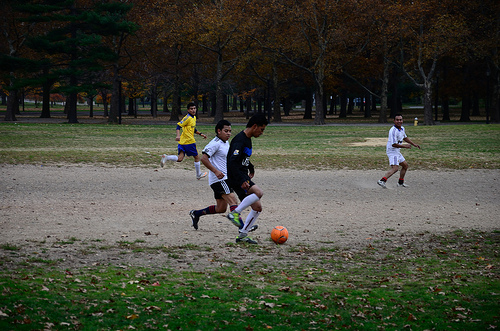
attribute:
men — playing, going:
[131, 70, 439, 243]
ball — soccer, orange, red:
[269, 224, 296, 247]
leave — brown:
[228, 250, 279, 302]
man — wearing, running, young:
[202, 95, 286, 236]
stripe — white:
[63, 149, 105, 157]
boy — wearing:
[358, 84, 427, 209]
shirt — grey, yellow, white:
[203, 130, 236, 194]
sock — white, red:
[234, 192, 255, 203]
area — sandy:
[26, 160, 142, 227]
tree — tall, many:
[4, 16, 151, 148]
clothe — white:
[203, 135, 234, 177]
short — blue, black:
[188, 135, 206, 154]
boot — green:
[229, 213, 248, 224]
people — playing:
[155, 93, 425, 215]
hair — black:
[216, 112, 234, 130]